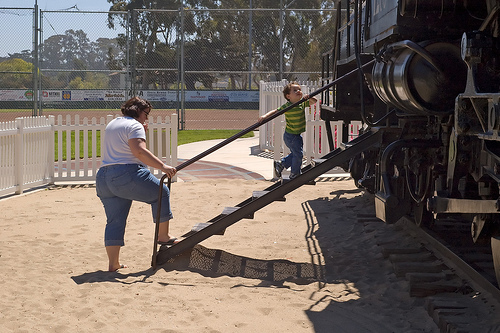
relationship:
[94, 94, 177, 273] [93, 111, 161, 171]
lady with white shirt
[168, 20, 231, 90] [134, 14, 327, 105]
wall on side of building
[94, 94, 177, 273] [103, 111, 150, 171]
lady wearing white shirt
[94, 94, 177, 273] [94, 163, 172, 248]
lady wearing pants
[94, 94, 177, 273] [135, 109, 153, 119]
lady wearing eyeglasses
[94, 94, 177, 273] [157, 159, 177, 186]
lady has hand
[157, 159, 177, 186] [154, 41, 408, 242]
hand on handrail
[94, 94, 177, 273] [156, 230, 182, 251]
lady has foot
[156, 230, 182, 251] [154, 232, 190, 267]
foot on step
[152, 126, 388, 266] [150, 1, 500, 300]
stairs are on train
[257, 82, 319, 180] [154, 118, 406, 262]
boy on steps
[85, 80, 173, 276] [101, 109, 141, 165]
lady wearing a shirt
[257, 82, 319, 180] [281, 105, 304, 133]
boy wearing a shirt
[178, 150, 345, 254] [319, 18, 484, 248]
stairs going up to train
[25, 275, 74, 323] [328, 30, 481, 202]
sand next to train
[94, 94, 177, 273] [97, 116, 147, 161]
lady wearing shirt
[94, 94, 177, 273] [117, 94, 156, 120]
lady with hair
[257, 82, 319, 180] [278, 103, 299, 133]
boy wearing shirt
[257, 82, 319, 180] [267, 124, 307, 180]
boy wearing pants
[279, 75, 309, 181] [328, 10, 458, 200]
boy entering train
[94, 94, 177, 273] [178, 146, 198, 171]
lady holding rail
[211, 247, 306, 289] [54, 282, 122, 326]
shadow on ground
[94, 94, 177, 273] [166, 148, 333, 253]
lady going up stairs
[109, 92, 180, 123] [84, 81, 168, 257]
head of woman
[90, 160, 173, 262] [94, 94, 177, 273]
pants of lady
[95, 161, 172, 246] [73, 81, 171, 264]
legs of woman